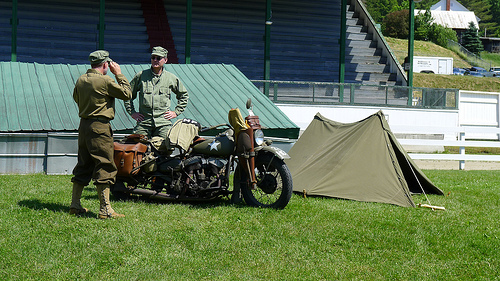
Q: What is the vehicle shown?
A: Motorcycle.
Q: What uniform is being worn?
A: Military uniform.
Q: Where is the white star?
A: On the motorcycle tank.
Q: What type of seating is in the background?
A: Bleachers.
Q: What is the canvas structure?
A: A tent.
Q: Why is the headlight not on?
A: Motorcycle not on.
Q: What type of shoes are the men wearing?
A: Combat boots.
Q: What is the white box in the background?
A: A trailer.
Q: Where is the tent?
A: On the grass.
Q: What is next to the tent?
A: The motorcycle.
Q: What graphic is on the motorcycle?
A: A white star.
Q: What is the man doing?
A: Saluting.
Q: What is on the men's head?
A: Green military hats.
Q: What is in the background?
A: Bleachers with green support posts.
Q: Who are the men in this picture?
A: Soldiers.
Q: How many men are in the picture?
A: Two.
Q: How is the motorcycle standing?
A: Upright.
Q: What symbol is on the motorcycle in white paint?
A: Star.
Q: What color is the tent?
A: Green.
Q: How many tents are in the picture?
A: One.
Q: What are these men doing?
A: Talking.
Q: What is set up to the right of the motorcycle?
A: Tent.